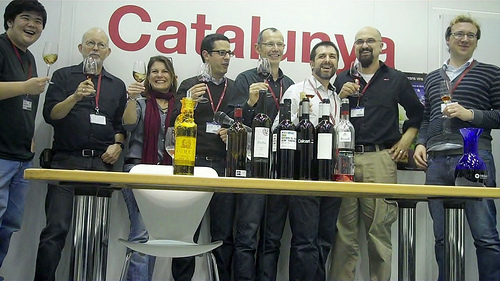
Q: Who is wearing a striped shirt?
A: Man on far right.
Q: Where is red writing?
A: On a white sign.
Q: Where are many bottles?
A: On table.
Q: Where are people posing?
A: Behind the table.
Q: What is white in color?
A: Chair.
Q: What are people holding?
A: Glasses.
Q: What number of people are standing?
A: Eight.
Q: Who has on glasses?
A: Man on far right.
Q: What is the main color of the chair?
A: White.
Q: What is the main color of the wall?
A: White.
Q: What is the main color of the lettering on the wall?
A: Red.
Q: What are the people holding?
A: Alcohol.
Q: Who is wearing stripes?
A: The man on the right.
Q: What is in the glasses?
A: Alcohol.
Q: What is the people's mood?
A: Happy.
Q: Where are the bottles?
A: On the table.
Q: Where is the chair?
A: Behind the table.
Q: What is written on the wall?
A: Catalunya.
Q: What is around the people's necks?
A: Name Tags.